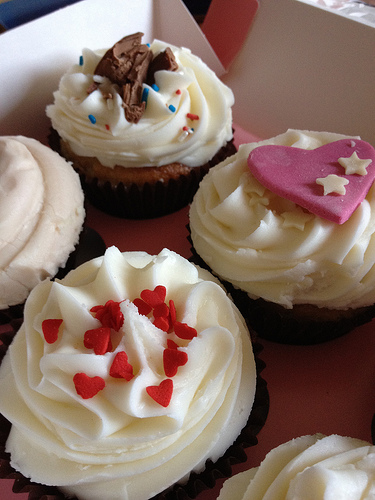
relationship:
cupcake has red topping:
[0, 245, 264, 499] [141, 272, 165, 411]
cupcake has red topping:
[0, 245, 264, 499] [33, 296, 164, 398]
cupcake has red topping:
[2, 245, 275, 494] [186, 110, 200, 122]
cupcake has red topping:
[186, 126, 374, 342] [174, 86, 183, 94]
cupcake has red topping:
[45, 27, 239, 223] [103, 121, 111, 129]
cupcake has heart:
[2, 245, 275, 494] [245, 133, 374, 227]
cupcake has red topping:
[186, 126, 374, 342] [144, 377, 175, 408]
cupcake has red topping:
[45, 27, 239, 223] [107, 350, 135, 383]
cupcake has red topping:
[2, 245, 275, 494] [83, 324, 111, 354]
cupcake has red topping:
[186, 126, 374, 342] [71, 370, 105, 401]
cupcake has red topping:
[45, 27, 239, 223] [41, 317, 61, 343]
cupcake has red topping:
[2, 245, 275, 494] [160, 346, 186, 377]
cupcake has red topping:
[186, 126, 374, 342] [171, 322, 196, 339]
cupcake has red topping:
[45, 27, 239, 223] [153, 300, 176, 333]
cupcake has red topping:
[2, 245, 275, 494] [140, 284, 167, 305]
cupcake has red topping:
[186, 126, 374, 342] [85, 300, 126, 330]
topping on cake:
[84, 326, 110, 352] [2, 241, 264, 498]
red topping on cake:
[140, 282, 168, 308] [10, 256, 259, 482]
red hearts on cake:
[40, 286, 196, 407] [124, 296, 148, 320]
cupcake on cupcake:
[0, 135, 93, 328] [2, 245, 275, 494]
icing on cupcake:
[187, 207, 370, 286] [45, 30, 219, 191]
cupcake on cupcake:
[0, 135, 93, 328] [187, 122, 374, 315]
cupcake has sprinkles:
[45, 27, 239, 223] [78, 40, 200, 128]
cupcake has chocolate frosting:
[45, 27, 239, 223] [94, 31, 177, 127]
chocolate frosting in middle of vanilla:
[94, 31, 177, 127] [45, 40, 233, 163]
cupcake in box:
[45, 27, 239, 223] [4, 6, 362, 163]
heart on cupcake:
[245, 133, 374, 227] [191, 120, 366, 339]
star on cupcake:
[314, 171, 352, 196] [191, 120, 366, 339]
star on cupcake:
[336, 152, 371, 177] [191, 120, 366, 339]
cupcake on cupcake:
[45, 27, 239, 223] [52, 32, 233, 190]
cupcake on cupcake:
[0, 245, 264, 499] [6, 247, 249, 498]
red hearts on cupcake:
[40, 286, 196, 407] [6, 247, 249, 498]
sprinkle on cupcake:
[145, 378, 173, 409] [2, 245, 275, 494]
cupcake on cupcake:
[45, 27, 239, 223] [45, 27, 239, 223]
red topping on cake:
[83, 327, 113, 353] [2, 241, 264, 498]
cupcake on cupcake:
[0, 245, 264, 499] [2, 245, 275, 494]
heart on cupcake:
[256, 131, 369, 242] [186, 126, 374, 350]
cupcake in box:
[216, 430, 373, 498] [150, 1, 373, 84]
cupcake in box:
[2, 245, 275, 494] [150, 1, 373, 84]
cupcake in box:
[186, 126, 374, 342] [150, 1, 373, 84]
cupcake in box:
[45, 27, 239, 223] [150, 1, 373, 84]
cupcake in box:
[0, 135, 108, 332] [150, 1, 373, 84]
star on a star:
[336, 152, 371, 177] [315, 173, 349, 197]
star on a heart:
[336, 152, 371, 177] [245, 133, 374, 227]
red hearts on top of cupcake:
[40, 286, 196, 407] [0, 245, 264, 499]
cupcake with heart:
[2, 245, 275, 494] [162, 346, 187, 376]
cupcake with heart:
[2, 245, 275, 494] [73, 371, 106, 399]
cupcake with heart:
[2, 245, 275, 494] [109, 350, 134, 378]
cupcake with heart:
[2, 245, 275, 494] [40, 318, 63, 342]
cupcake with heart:
[2, 245, 275, 494] [139, 285, 167, 306]